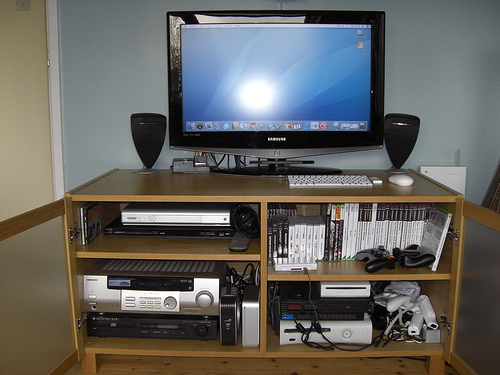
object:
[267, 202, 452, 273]
game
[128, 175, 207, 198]
wooden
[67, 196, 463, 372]
center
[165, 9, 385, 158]
tv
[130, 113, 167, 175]
speaker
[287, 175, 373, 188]
keyboard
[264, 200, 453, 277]
shelf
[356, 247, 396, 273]
controller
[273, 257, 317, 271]
white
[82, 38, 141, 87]
blue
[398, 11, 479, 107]
wall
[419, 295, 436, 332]
wii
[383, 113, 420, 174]
speakers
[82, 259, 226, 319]
stereo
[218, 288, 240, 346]
router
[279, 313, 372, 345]
console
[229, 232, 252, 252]
remote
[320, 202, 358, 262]
games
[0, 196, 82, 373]
doors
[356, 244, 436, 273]
black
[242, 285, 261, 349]
mac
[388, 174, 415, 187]
white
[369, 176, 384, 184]
white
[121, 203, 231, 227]
silver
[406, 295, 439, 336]
two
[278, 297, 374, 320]
playstation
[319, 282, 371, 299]
white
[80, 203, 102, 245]
dvd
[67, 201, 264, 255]
shelf